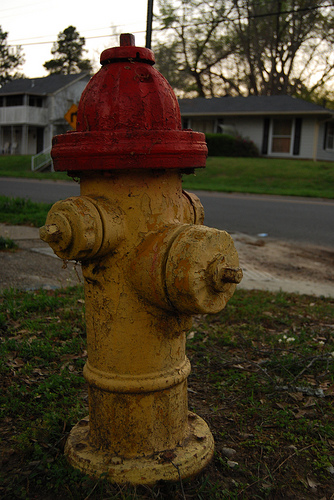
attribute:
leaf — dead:
[276, 397, 297, 412]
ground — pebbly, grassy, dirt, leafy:
[0, 196, 332, 499]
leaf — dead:
[11, 355, 28, 376]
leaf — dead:
[232, 360, 245, 371]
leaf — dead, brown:
[315, 333, 333, 348]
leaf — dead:
[304, 474, 321, 490]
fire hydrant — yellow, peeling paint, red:
[37, 30, 242, 490]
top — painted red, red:
[43, 27, 208, 170]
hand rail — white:
[28, 131, 59, 176]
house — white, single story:
[165, 94, 333, 173]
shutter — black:
[259, 112, 274, 155]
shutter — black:
[290, 115, 303, 157]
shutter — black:
[212, 115, 223, 137]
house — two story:
[2, 73, 97, 169]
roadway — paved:
[3, 177, 333, 252]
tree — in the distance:
[46, 26, 96, 81]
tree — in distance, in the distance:
[148, 2, 247, 98]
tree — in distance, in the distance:
[1, 26, 23, 84]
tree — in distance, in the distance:
[224, 2, 333, 109]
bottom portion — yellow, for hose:
[38, 172, 243, 482]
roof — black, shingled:
[176, 94, 326, 116]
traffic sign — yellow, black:
[63, 104, 82, 127]